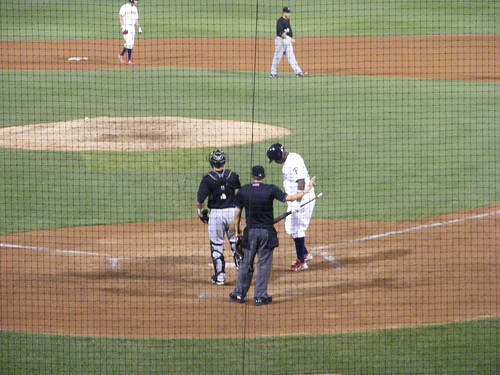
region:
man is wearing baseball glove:
[115, 2, 145, 66]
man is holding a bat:
[265, 142, 318, 274]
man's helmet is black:
[262, 141, 287, 167]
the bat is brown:
[272, 194, 322, 225]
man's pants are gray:
[205, 205, 243, 284]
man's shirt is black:
[236, 184, 288, 229]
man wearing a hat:
[268, 5, 310, 79]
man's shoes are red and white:
[291, 253, 314, 275]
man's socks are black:
[290, 233, 309, 264]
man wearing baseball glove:
[191, 148, 244, 287]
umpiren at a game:
[223, 159, 288, 310]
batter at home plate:
[259, 131, 332, 276]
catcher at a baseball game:
[190, 135, 250, 299]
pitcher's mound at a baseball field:
[31, 112, 240, 145]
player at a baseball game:
[261, 4, 318, 77]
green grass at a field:
[339, 96, 471, 185]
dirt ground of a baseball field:
[377, 249, 483, 309]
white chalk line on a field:
[364, 208, 479, 245]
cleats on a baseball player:
[281, 248, 321, 289]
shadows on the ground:
[320, 252, 407, 305]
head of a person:
[260, 133, 305, 161]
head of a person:
[276, 1, 304, 22]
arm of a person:
[282, 168, 317, 206]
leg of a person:
[216, 248, 257, 290]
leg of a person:
[245, 249, 289, 290]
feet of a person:
[216, 286, 247, 303]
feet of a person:
[247, 283, 279, 311]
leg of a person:
[203, 226, 235, 267]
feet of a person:
[200, 271, 235, 293]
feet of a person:
[283, 252, 323, 283]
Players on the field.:
[113, 3, 426, 339]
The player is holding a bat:
[268, 196, 353, 238]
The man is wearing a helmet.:
[268, 134, 288, 166]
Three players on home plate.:
[194, 137, 326, 307]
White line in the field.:
[344, 197, 491, 241]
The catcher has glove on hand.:
[188, 205, 209, 224]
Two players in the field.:
[110, 8, 367, 81]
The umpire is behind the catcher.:
[189, 167, 274, 304]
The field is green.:
[51, 70, 306, 123]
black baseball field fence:
[2, 3, 498, 371]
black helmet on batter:
[260, 138, 290, 170]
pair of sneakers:
[283, 248, 317, 275]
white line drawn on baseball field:
[1, 239, 116, 278]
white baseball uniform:
[272, 148, 329, 239]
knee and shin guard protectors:
[202, 234, 256, 284]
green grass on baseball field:
[4, 70, 496, 370]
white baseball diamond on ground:
[202, 253, 253, 278]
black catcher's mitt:
[192, 206, 212, 229]